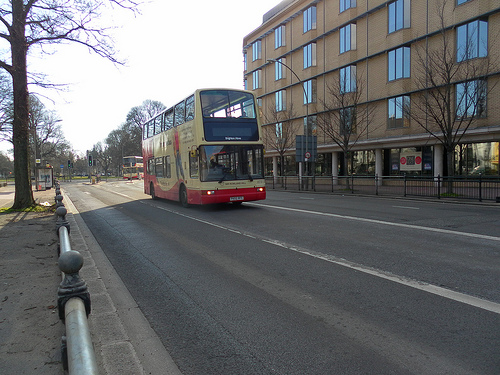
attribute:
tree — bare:
[316, 69, 385, 194]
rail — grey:
[51, 200, 94, 355]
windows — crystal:
[337, 21, 358, 54]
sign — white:
[292, 131, 322, 167]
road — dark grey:
[115, 205, 498, 372]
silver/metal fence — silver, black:
[47, 172, 104, 372]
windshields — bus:
[203, 144, 263, 180]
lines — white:
[221, 203, 393, 261]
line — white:
[85, 179, 499, 314]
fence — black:
[264, 172, 499, 206]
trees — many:
[3, 1, 163, 207]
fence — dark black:
[24, 163, 114, 372]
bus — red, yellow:
[131, 77, 270, 217]